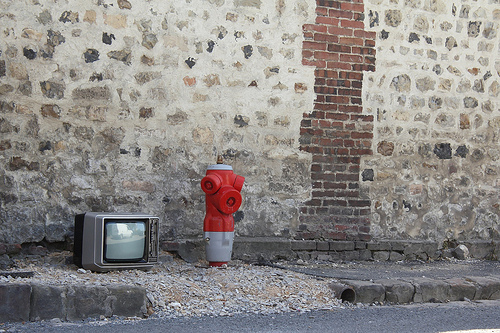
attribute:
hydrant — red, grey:
[192, 161, 255, 273]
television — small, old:
[76, 204, 154, 309]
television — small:
[57, 181, 146, 288]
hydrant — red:
[176, 155, 283, 305]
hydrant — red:
[181, 148, 271, 291]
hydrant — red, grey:
[190, 144, 275, 280]